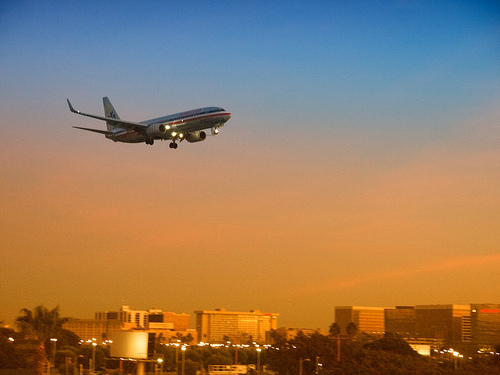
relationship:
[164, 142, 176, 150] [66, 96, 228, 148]
gear on airliner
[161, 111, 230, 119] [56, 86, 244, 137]
stripe on plane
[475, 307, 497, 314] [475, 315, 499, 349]
red lettering on building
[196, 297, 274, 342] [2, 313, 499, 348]
skyscaper on horizon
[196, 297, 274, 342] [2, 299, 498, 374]
skyscaper in city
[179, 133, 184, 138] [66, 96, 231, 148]
light in plane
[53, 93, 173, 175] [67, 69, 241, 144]
wings in plane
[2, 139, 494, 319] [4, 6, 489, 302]
cloud in sky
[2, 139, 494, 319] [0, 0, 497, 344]
cloud in sky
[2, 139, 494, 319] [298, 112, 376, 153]
cloud in sky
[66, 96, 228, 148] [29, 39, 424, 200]
airliner in flight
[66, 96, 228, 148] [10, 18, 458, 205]
airliner in flight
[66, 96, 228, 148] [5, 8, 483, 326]
airliner flying air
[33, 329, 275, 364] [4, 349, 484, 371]
lights shining street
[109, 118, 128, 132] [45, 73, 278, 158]
marks on plane